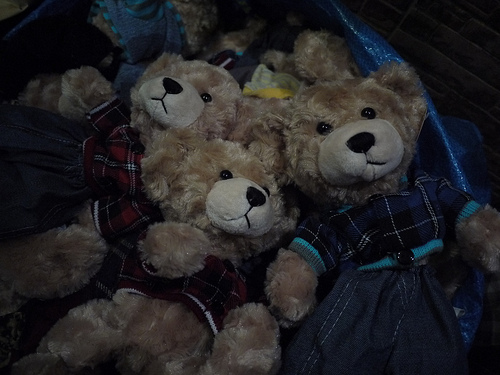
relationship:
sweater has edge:
[287, 165, 486, 279] [288, 236, 330, 279]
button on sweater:
[396, 248, 416, 267] [287, 165, 486, 279]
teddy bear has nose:
[263, 59, 500, 373] [346, 132, 377, 153]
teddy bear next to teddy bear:
[263, 59, 500, 373] [13, 140, 302, 373]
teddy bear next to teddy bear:
[13, 140, 302, 373] [3, 50, 264, 245]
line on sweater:
[382, 194, 405, 249] [287, 165, 486, 279]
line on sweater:
[344, 209, 374, 242] [287, 165, 486, 279]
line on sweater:
[384, 216, 446, 240] [287, 165, 486, 279]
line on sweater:
[417, 180, 441, 240] [287, 165, 486, 279]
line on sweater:
[297, 226, 337, 274] [287, 165, 486, 279]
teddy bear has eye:
[263, 59, 500, 373] [317, 119, 334, 137]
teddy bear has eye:
[263, 59, 500, 373] [363, 105, 378, 122]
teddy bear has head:
[263, 59, 500, 373] [257, 61, 428, 204]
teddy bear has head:
[13, 140, 302, 373] [159, 127, 288, 261]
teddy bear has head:
[3, 50, 264, 245] [126, 50, 256, 155]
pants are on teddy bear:
[0, 101, 98, 238] [3, 50, 264, 245]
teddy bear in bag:
[263, 59, 500, 373] [7, 3, 498, 374]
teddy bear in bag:
[13, 140, 302, 373] [7, 3, 498, 374]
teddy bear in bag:
[3, 50, 264, 245] [7, 3, 498, 374]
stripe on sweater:
[110, 286, 218, 337] [115, 221, 249, 349]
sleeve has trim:
[428, 174, 483, 231] [456, 199, 483, 230]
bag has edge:
[7, 3, 498, 374] [322, 1, 493, 203]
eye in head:
[317, 119, 334, 137] [257, 61, 428, 204]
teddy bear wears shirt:
[3, 50, 264, 245] [80, 93, 166, 243]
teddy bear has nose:
[13, 140, 302, 373] [245, 183, 267, 210]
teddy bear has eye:
[13, 140, 302, 373] [218, 167, 234, 179]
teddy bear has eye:
[13, 140, 302, 373] [262, 183, 271, 197]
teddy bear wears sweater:
[263, 59, 500, 373] [287, 165, 486, 279]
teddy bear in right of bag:
[263, 59, 500, 373] [7, 3, 498, 374]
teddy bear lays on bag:
[263, 59, 500, 373] [7, 3, 498, 374]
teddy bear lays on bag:
[13, 140, 302, 373] [7, 3, 498, 374]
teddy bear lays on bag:
[3, 50, 264, 245] [7, 3, 498, 374]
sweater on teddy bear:
[287, 165, 486, 279] [263, 59, 500, 373]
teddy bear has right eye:
[13, 140, 302, 373] [218, 167, 234, 179]